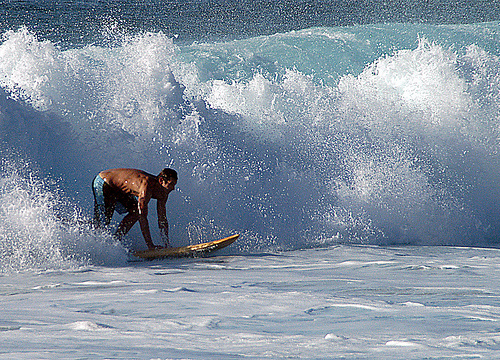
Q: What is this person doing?
A: Surfing.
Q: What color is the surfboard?
A: Yellow.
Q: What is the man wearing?
A: Swim trunks.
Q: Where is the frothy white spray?
A: In front of the teal colored wave.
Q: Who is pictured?
A: A tanned surfer.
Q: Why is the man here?
A: He is surfing.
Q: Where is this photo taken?
A: In the ocean.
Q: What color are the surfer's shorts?
A: Blue.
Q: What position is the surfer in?
A: Crouched.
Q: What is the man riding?
A: A surfboard.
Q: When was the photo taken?
A: Daylight.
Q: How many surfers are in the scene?
A: One.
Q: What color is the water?
A: White.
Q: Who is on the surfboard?
A: Tan surfer.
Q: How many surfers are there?
A: 1.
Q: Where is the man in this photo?
A: In the ocean.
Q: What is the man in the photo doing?
A: Surfing.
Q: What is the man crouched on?
A: A surfboard.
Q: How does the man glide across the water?
A: The force of the wave pushes him.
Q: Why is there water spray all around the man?
A: The wave is crashing.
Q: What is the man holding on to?
A: A surfboard.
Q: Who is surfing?
A: A man.